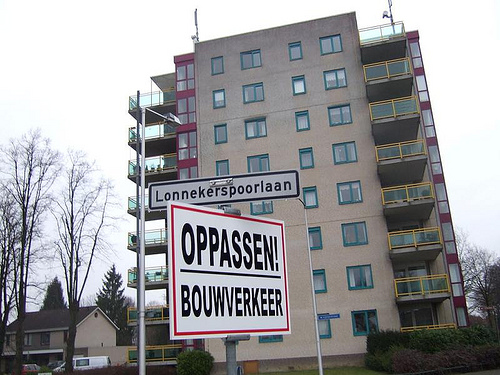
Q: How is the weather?
A: It is cloudless.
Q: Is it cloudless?
A: Yes, it is cloudless.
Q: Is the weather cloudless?
A: Yes, it is cloudless.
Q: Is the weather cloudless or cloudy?
A: It is cloudless.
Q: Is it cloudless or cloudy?
A: It is cloudless.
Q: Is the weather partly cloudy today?
A: No, it is cloudless.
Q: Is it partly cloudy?
A: No, it is cloudless.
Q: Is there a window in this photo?
A: Yes, there is a window.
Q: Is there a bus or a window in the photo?
A: Yes, there is a window.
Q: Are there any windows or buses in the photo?
A: Yes, there is a window.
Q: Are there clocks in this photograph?
A: No, there are no clocks.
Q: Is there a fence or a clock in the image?
A: No, there are no clocks or fences.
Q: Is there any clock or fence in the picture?
A: No, there are no clocks or fences.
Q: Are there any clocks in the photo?
A: No, there are no clocks.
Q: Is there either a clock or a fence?
A: No, there are no clocks or fences.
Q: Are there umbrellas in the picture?
A: No, there are no umbrellas.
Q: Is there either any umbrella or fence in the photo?
A: No, there are no umbrellas or fences.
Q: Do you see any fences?
A: No, there are no fences.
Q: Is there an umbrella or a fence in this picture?
A: No, there are no fences or umbrellas.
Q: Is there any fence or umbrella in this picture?
A: No, there are no fences or umbrellas.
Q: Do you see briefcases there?
A: No, there are no briefcases.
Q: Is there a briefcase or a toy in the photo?
A: No, there are no briefcases or toys.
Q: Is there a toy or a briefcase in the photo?
A: No, there are no briefcases or toys.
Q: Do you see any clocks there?
A: No, there are no clocks.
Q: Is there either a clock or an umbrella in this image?
A: No, there are no clocks or umbrellas.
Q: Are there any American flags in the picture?
A: No, there are no American flags.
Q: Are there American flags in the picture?
A: No, there are no American flags.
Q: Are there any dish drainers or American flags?
A: No, there are no American flags or dish drainers.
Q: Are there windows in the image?
A: Yes, there is a window.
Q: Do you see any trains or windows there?
A: Yes, there is a window.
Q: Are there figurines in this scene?
A: No, there are no figurines.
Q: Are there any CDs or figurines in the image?
A: No, there are no figurines or cds.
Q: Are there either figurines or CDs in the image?
A: No, there are no figurines or cds.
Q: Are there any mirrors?
A: No, there are no mirrors.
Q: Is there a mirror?
A: No, there are no mirrors.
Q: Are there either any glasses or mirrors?
A: No, there are no mirrors or glasses.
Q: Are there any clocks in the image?
A: No, there are no clocks.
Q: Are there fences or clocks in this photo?
A: No, there are no clocks or fences.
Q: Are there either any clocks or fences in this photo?
A: No, there are no clocks or fences.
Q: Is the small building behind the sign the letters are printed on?
A: Yes, the building is behind the sign.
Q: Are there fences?
A: No, there are no fences.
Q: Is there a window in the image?
A: Yes, there is a window.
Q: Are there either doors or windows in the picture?
A: Yes, there is a window.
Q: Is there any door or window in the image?
A: Yes, there is a window.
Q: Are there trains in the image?
A: No, there are no trains.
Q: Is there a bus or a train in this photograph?
A: No, there are no trains or buses.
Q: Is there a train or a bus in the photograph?
A: No, there are no trains or buses.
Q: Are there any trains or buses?
A: No, there are no trains or buses.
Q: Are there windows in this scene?
A: Yes, there is a window.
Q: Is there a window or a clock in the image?
A: Yes, there is a window.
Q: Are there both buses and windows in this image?
A: No, there is a window but no buses.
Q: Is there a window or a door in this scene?
A: Yes, there is a window.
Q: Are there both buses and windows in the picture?
A: No, there is a window but no buses.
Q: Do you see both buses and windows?
A: No, there is a window but no buses.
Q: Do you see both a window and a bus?
A: No, there is a window but no buses.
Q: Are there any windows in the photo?
A: Yes, there is a window.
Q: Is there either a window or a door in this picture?
A: Yes, there is a window.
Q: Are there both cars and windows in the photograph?
A: Yes, there are both a window and a car.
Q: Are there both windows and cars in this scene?
A: Yes, there are both a window and a car.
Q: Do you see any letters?
A: Yes, there are letters.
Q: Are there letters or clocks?
A: Yes, there are letters.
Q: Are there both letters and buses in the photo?
A: No, there are letters but no buses.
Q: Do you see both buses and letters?
A: No, there are letters but no buses.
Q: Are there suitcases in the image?
A: No, there are no suitcases.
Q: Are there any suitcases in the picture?
A: No, there are no suitcases.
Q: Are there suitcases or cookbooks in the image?
A: No, there are no suitcases or cookbooks.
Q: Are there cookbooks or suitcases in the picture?
A: No, there are no suitcases or cookbooks.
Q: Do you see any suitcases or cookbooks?
A: No, there are no suitcases or cookbooks.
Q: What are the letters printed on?
A: The letters are printed on the sign.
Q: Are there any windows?
A: Yes, there is a window.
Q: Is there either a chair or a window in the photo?
A: Yes, there is a window.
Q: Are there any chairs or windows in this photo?
A: Yes, there is a window.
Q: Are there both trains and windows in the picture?
A: No, there is a window but no trains.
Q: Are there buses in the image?
A: No, there are no buses.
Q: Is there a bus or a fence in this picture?
A: No, there are no buses or fences.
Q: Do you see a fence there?
A: No, there are no fences.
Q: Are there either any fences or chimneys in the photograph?
A: No, there are no fences or chimneys.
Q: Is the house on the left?
A: Yes, the house is on the left of the image.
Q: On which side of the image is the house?
A: The house is on the left of the image.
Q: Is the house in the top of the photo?
A: No, the house is in the bottom of the image.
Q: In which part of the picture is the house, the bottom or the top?
A: The house is in the bottom of the image.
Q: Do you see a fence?
A: No, there are no fences.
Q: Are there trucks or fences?
A: No, there are no fences or trucks.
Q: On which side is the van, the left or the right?
A: The van is on the left of the image.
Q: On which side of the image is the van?
A: The van is on the left of the image.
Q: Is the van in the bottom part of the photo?
A: Yes, the van is in the bottom of the image.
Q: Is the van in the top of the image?
A: No, the van is in the bottom of the image.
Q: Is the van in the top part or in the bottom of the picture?
A: The van is in the bottom of the image.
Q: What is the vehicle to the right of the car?
A: The vehicle is a van.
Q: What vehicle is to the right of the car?
A: The vehicle is a van.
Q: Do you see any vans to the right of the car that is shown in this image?
A: Yes, there is a van to the right of the car.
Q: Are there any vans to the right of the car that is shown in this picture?
A: Yes, there is a van to the right of the car.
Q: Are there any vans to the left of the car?
A: No, the van is to the right of the car.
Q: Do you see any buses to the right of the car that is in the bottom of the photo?
A: No, there is a van to the right of the car.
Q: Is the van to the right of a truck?
A: No, the van is to the right of the car.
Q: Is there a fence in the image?
A: No, there are no fences.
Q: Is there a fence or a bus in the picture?
A: No, there are no fences or buses.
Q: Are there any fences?
A: No, there are no fences.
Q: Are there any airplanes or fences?
A: No, there are no fences or airplanes.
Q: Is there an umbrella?
A: No, there are no umbrellas.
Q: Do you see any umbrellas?
A: No, there are no umbrellas.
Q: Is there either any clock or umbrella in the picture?
A: No, there are no umbrellas or clocks.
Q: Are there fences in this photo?
A: No, there are no fences.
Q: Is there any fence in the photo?
A: No, there are no fences.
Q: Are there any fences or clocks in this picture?
A: No, there are no fences or clocks.